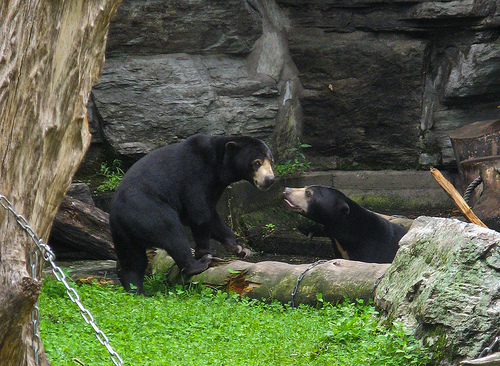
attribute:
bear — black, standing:
[110, 132, 272, 292]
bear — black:
[285, 185, 429, 272]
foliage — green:
[91, 288, 375, 359]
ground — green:
[14, 227, 499, 362]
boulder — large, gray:
[375, 218, 499, 365]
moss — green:
[438, 245, 482, 316]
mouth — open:
[279, 188, 316, 221]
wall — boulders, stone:
[101, 3, 498, 164]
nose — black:
[262, 175, 277, 187]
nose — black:
[278, 186, 289, 196]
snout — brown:
[246, 161, 276, 192]